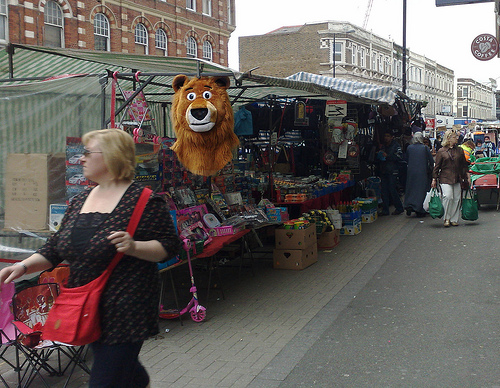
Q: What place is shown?
A: It is a sidewalk.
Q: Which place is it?
A: It is a sidewalk.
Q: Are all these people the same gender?
A: Yes, all the people are female.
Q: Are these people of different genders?
A: No, all the people are female.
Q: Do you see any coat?
A: Yes, there is a coat.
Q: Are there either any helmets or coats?
A: Yes, there is a coat.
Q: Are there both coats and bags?
A: Yes, there are both a coat and a bag.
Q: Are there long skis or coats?
A: Yes, there is a long coat.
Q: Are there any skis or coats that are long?
A: Yes, the coat is long.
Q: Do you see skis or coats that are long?
A: Yes, the coat is long.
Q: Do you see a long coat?
A: Yes, there is a long coat.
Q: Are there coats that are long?
A: Yes, there is a coat that is long.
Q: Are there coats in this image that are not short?
A: Yes, there is a long coat.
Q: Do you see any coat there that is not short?
A: Yes, there is a long coat.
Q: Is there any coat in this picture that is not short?
A: Yes, there is a long coat.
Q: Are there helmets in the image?
A: No, there are no helmets.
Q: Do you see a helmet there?
A: No, there are no helmets.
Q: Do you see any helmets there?
A: No, there are no helmets.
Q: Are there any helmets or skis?
A: No, there are no helmets or skis.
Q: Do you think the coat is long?
A: Yes, the coat is long.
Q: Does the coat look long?
A: Yes, the coat is long.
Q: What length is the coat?
A: The coat is long.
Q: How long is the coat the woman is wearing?
A: The coat is long.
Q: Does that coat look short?
A: No, the coat is long.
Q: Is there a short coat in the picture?
A: No, there is a coat but it is long.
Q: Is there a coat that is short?
A: No, there is a coat but it is long.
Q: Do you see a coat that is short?
A: No, there is a coat but it is long.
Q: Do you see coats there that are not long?
A: No, there is a coat but it is long.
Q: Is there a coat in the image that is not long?
A: No, there is a coat but it is long.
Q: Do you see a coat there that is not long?
A: No, there is a coat but it is long.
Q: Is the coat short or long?
A: The coat is long.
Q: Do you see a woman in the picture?
A: Yes, there is a woman.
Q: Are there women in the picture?
A: Yes, there is a woman.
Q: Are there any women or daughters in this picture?
A: Yes, there is a woman.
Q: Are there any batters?
A: No, there are no batters.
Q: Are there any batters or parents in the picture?
A: No, there are no batters or parents.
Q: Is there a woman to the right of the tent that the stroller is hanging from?
A: Yes, there is a woman to the right of the tent.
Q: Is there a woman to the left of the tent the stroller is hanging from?
A: No, the woman is to the right of the tent.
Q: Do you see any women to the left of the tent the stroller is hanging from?
A: No, the woman is to the right of the tent.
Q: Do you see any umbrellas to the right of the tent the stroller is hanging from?
A: No, there is a woman to the right of the tent.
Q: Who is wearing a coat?
A: The woman is wearing a coat.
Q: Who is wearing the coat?
A: The woman is wearing a coat.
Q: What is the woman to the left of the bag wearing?
A: The woman is wearing a coat.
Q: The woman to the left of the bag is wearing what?
A: The woman is wearing a coat.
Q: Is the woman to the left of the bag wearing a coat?
A: Yes, the woman is wearing a coat.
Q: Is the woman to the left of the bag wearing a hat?
A: No, the woman is wearing a coat.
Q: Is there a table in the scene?
A: Yes, there is a table.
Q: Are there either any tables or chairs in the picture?
A: Yes, there is a table.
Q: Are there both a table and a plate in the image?
A: No, there is a table but no plates.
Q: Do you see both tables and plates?
A: No, there is a table but no plates.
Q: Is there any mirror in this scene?
A: No, there are no mirrors.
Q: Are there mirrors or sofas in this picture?
A: No, there are no mirrors or sofas.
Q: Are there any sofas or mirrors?
A: No, there are no mirrors or sofas.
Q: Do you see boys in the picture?
A: No, there are no boys.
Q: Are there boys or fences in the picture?
A: No, there are no boys or fences.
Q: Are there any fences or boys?
A: No, there are no boys or fences.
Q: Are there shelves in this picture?
A: No, there are no shelves.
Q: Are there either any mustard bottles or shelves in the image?
A: No, there are no shelves or mustard bottles.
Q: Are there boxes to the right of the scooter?
A: Yes, there are boxes to the right of the scooter.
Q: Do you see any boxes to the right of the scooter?
A: Yes, there are boxes to the right of the scooter.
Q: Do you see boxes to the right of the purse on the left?
A: Yes, there are boxes to the right of the purse.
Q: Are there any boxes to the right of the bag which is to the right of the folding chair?
A: Yes, there are boxes to the right of the purse.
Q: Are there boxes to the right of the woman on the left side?
A: Yes, there are boxes to the right of the woman.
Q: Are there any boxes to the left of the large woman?
A: No, the boxes are to the right of the woman.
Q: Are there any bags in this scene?
A: Yes, there is a bag.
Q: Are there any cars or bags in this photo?
A: Yes, there is a bag.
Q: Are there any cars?
A: No, there are no cars.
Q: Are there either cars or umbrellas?
A: No, there are no cars or umbrellas.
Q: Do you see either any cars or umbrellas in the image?
A: No, there are no cars or umbrellas.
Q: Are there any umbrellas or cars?
A: No, there are no cars or umbrellas.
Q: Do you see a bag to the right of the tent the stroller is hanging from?
A: Yes, there is a bag to the right of the tent.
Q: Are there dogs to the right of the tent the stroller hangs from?
A: No, there is a bag to the right of the tent.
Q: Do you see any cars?
A: No, there are no cars.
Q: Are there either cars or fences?
A: No, there are no cars or fences.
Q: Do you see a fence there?
A: No, there are no fences.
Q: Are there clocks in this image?
A: No, there are no clocks.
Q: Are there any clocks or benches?
A: No, there are no clocks or benches.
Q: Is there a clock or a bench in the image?
A: No, there are no clocks or benches.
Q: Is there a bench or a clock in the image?
A: No, there are no clocks or benches.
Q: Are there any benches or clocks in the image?
A: No, there are no clocks or benches.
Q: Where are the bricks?
A: The bricks are on the side walk.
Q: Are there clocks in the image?
A: No, there are no clocks.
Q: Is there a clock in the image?
A: No, there are no clocks.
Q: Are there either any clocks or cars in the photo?
A: No, there are no clocks or cars.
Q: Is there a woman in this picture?
A: Yes, there is a woman.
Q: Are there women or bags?
A: Yes, there is a woman.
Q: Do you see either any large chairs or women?
A: Yes, there is a large woman.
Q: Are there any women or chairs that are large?
A: Yes, the woman is large.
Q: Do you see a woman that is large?
A: Yes, there is a large woman.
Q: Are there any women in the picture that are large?
A: Yes, there is a woman that is large.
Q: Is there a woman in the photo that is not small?
A: Yes, there is a large woman.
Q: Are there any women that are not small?
A: Yes, there is a large woman.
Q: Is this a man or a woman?
A: This is a woman.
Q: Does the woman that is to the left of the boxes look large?
A: Yes, the woman is large.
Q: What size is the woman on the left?
A: The woman is large.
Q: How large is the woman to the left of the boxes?
A: The woman is large.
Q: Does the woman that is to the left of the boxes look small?
A: No, the woman is large.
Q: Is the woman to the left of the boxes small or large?
A: The woman is large.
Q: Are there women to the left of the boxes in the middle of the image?
A: Yes, there is a woman to the left of the boxes.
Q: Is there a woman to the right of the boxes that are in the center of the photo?
A: No, the woman is to the left of the boxes.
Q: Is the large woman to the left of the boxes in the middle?
A: Yes, the woman is to the left of the boxes.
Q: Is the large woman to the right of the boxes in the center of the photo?
A: No, the woman is to the left of the boxes.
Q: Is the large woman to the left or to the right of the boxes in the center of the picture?
A: The woman is to the left of the boxes.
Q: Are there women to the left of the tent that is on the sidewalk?
A: Yes, there is a woman to the left of the tent.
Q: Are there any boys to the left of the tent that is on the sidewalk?
A: No, there is a woman to the left of the tent.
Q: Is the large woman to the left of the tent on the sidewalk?
A: Yes, the woman is to the left of the tent.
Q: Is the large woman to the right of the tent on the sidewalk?
A: No, the woman is to the left of the tent.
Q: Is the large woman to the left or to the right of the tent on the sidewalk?
A: The woman is to the left of the tent.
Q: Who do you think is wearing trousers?
A: The woman is wearing trousers.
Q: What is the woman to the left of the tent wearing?
A: The woman is wearing pants.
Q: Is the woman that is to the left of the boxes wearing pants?
A: Yes, the woman is wearing pants.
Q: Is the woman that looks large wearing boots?
A: No, the woman is wearing pants.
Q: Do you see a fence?
A: No, there are no fences.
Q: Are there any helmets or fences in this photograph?
A: No, there are no fences or helmets.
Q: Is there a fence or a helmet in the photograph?
A: No, there are no fences or helmets.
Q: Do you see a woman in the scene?
A: Yes, there is a woman.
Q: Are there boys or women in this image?
A: Yes, there is a woman.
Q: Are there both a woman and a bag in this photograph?
A: Yes, there are both a woman and a bag.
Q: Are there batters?
A: No, there are no batters.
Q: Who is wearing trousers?
A: The woman is wearing trousers.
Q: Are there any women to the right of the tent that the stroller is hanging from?
A: Yes, there is a woman to the right of the tent.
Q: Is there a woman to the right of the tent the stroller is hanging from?
A: Yes, there is a woman to the right of the tent.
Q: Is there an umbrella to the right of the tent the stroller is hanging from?
A: No, there is a woman to the right of the tent.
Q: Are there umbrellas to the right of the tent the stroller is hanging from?
A: No, there is a woman to the right of the tent.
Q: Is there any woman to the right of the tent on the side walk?
A: Yes, there is a woman to the right of the tent.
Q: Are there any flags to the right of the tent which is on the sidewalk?
A: No, there is a woman to the right of the tent.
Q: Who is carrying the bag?
A: The woman is carrying the bag.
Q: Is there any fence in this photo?
A: No, there are no fences.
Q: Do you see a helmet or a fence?
A: No, there are no fences or helmets.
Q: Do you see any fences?
A: No, there are no fences.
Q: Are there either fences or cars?
A: No, there are no fences or cars.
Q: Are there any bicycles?
A: No, there are no bicycles.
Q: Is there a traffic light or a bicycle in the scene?
A: No, there are no bicycles or traffic lights.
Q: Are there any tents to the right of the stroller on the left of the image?
A: Yes, there is a tent to the right of the stroller.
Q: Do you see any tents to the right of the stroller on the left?
A: Yes, there is a tent to the right of the stroller.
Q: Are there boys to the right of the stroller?
A: No, there is a tent to the right of the stroller.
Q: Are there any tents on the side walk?
A: Yes, there is a tent on the side walk.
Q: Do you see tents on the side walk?
A: Yes, there is a tent on the side walk.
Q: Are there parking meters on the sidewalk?
A: No, there is a tent on the sidewalk.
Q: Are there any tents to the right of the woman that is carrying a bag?
A: No, the tent is to the left of the woman.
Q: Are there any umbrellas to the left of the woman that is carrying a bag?
A: No, there is a tent to the left of the woman.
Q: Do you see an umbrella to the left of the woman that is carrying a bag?
A: No, there is a tent to the left of the woman.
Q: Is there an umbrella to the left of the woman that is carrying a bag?
A: No, there is a tent to the left of the woman.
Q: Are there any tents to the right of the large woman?
A: Yes, there is a tent to the right of the woman.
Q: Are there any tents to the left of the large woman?
A: No, the tent is to the right of the woman.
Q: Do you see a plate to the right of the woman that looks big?
A: No, there is a tent to the right of the woman.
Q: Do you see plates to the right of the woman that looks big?
A: No, there is a tent to the right of the woman.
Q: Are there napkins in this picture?
A: No, there are no napkins.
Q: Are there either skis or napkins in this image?
A: No, there are no napkins or skis.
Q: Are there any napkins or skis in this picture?
A: No, there are no napkins or skis.